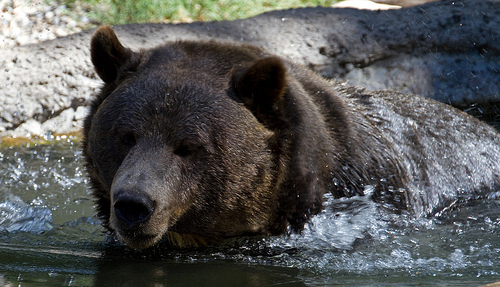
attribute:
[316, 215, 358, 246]
water — brown, cool, white, gree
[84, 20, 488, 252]
bear — brown, black, wet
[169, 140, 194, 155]
eye — black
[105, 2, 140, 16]
grass — gree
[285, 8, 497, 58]
log — black